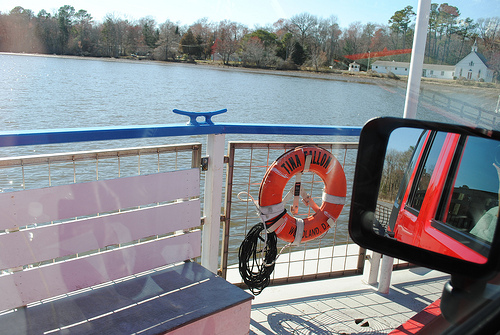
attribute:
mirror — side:
[347, 116, 499, 283]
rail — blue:
[1, 108, 362, 148]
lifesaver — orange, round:
[256, 146, 347, 245]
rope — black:
[239, 222, 277, 295]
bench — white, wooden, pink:
[0, 168, 255, 334]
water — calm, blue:
[0, 53, 499, 270]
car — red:
[347, 116, 498, 335]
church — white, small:
[453, 36, 495, 84]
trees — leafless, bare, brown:
[290, 13, 329, 72]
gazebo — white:
[347, 60, 360, 73]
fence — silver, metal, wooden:
[1, 141, 422, 289]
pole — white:
[401, 1, 432, 120]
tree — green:
[36, 5, 76, 55]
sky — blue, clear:
[1, 0, 499, 42]